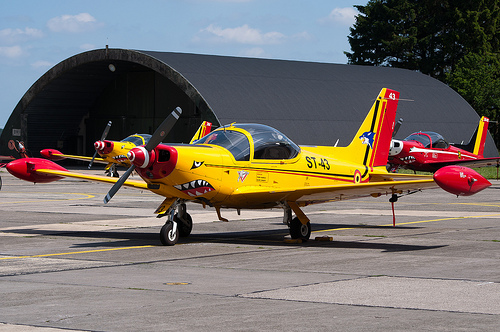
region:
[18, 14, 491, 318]
A small size flights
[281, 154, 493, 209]
Red and yellow color of the wings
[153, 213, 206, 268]
Front wheel of the flight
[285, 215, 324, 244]
Back side wheel of the flight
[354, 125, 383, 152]
Logo of the flight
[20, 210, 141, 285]
Runway marked with yellow line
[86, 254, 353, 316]
Concrete runway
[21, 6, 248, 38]
A blue sky with clouds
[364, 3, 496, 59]
Tree near the airport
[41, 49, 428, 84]
A metal roof building near the runway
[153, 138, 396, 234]
small yellow and red plane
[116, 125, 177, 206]
black propeller on plane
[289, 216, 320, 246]
black tire on plane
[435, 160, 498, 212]
red tip of airplane wing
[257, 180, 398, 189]
airplane has yellow wing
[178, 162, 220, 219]
plane has sharp teeth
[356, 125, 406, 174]
wolf on planes tail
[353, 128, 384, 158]
wolf is blue and white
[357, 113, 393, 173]
tail is red and yellow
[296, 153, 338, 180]
letters st-43 on plane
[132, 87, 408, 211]
the plane is made of metal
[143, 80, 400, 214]
the plane is yellow in color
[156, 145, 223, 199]
the plane has an animal design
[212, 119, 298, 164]
the plane has a canopy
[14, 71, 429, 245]
the plane is on a pavement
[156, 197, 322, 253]
the plane's wheels are opened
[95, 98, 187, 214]
the propeller is at an angle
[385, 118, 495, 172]
the plane is behind the yellow plane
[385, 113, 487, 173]
the plane is red in color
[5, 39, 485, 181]
the hangar is behind the planes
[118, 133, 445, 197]
this is a jet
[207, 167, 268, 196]
the jet is yellow in color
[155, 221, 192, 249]
this is the wheel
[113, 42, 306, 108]
this is a building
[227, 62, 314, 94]
the roof is black in color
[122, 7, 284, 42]
this is the sky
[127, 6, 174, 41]
the sky is blue in color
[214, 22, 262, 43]
these are the clouds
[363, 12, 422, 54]
this is a tree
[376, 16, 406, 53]
the leaves are green in color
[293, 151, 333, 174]
black number on plane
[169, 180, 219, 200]
mouth design on plane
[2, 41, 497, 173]
dark gray hanger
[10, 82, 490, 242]
yellow and red plane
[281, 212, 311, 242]
back wheel of yellow plane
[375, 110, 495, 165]
red white and yellow plane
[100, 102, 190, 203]
propeller on plane in front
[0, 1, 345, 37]
blue sky with clouds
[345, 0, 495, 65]
dark green tall trees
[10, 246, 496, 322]
ground pavement for plane